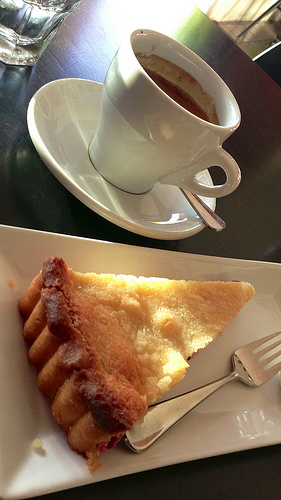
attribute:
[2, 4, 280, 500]
image — slanted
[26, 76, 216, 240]
dish — small, white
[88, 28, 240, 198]
beverage — hot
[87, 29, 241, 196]
mug — white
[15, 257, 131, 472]
crust — crispy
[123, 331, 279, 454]
fork — silver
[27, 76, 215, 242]
plate — white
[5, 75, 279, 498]
plates — white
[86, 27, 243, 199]
cup — white, glass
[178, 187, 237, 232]
teaspoon — steel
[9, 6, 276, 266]
table — brown, black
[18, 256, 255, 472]
pie — baked, sliced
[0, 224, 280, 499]
dish — rectangular